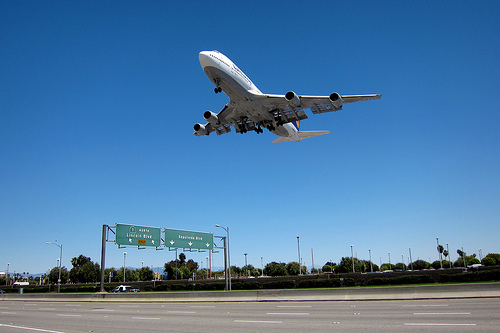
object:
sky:
[0, 0, 499, 279]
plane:
[190, 49, 382, 143]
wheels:
[211, 87, 219, 95]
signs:
[163, 228, 212, 251]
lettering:
[175, 234, 203, 241]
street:
[0, 295, 499, 332]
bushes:
[478, 257, 497, 266]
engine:
[283, 91, 301, 109]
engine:
[201, 110, 217, 125]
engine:
[191, 123, 206, 135]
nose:
[197, 49, 206, 59]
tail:
[270, 130, 330, 146]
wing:
[254, 90, 382, 116]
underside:
[192, 62, 379, 143]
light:
[213, 223, 232, 290]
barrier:
[0, 282, 499, 301]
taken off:
[191, 49, 382, 145]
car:
[111, 284, 135, 294]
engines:
[328, 92, 342, 110]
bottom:
[0, 255, 498, 332]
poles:
[98, 224, 108, 292]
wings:
[191, 101, 250, 137]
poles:
[221, 237, 229, 290]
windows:
[207, 53, 212, 59]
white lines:
[231, 319, 283, 324]